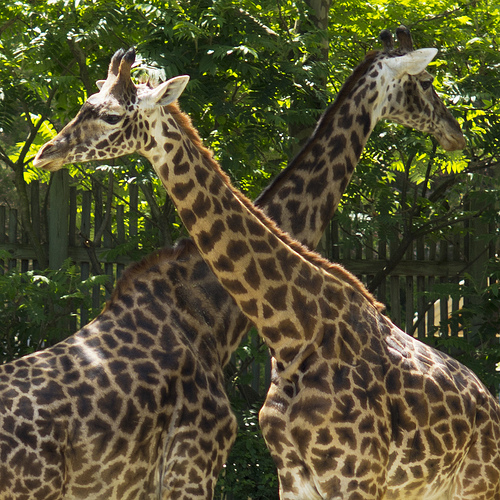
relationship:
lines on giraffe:
[326, 350, 422, 446] [16, 35, 498, 497]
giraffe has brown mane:
[16, 35, 498, 497] [131, 66, 388, 314]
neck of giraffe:
[147, 105, 377, 346] [16, 35, 498, 497]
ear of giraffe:
[149, 81, 196, 121] [16, 73, 423, 367]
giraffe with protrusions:
[16, 35, 498, 497] [380, 25, 412, 55]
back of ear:
[390, 52, 433, 72] [383, 46, 439, 76]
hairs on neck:
[333, 265, 375, 296] [172, 144, 410, 346]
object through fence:
[404, 257, 470, 346] [47, 208, 190, 332]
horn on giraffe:
[98, 33, 120, 78] [16, 35, 498, 497]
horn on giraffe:
[112, 44, 140, 91] [16, 35, 498, 497]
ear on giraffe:
[149, 81, 196, 121] [16, 35, 498, 497]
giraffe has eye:
[16, 35, 498, 497] [94, 102, 127, 138]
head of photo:
[27, 35, 198, 181] [69, 49, 146, 167]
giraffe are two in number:
[16, 35, 498, 497] [48, 185, 415, 389]